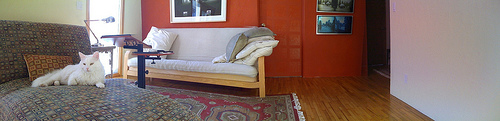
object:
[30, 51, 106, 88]
cat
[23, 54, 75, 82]
pillow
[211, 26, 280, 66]
pillows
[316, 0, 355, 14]
picture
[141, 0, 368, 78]
wall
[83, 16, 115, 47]
lamp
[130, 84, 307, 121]
rug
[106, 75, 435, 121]
floor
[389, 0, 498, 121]
wall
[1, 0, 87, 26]
wall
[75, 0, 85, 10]
light switch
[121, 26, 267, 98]
futon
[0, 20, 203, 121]
bed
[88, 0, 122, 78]
window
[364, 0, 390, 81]
doorway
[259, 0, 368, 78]
door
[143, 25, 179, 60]
pillow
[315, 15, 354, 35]
picture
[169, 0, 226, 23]
picture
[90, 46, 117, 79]
table